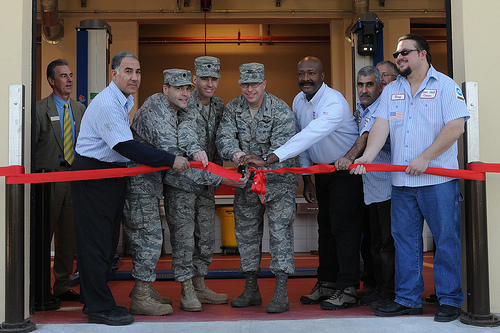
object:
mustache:
[299, 81, 315, 86]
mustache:
[360, 93, 371, 98]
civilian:
[70, 51, 190, 325]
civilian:
[30, 56, 86, 314]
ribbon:
[8, 160, 498, 194]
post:
[1, 166, 24, 330]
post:
[465, 160, 487, 322]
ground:
[199, 317, 463, 333]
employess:
[348, 34, 470, 322]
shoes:
[320, 285, 362, 310]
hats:
[162, 68, 195, 87]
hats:
[194, 55, 221, 78]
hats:
[238, 62, 265, 85]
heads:
[163, 69, 196, 110]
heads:
[192, 55, 221, 98]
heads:
[239, 62, 267, 103]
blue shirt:
[371, 65, 467, 186]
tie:
[61, 102, 77, 165]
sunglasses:
[393, 47, 426, 58]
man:
[283, 54, 355, 170]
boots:
[129, 280, 174, 316]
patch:
[455, 86, 465, 102]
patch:
[420, 89, 437, 99]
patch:
[391, 94, 404, 101]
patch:
[390, 111, 403, 120]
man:
[214, 62, 299, 312]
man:
[164, 55, 229, 310]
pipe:
[141, 35, 330, 44]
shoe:
[433, 303, 463, 323]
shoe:
[373, 304, 423, 317]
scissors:
[237, 165, 258, 180]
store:
[10, 0, 484, 323]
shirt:
[276, 82, 360, 165]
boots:
[265, 274, 289, 312]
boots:
[230, 271, 263, 307]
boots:
[192, 277, 228, 304]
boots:
[179, 280, 203, 312]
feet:
[265, 290, 288, 313]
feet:
[229, 290, 264, 307]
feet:
[196, 290, 232, 305]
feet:
[180, 293, 203, 311]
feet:
[127, 291, 173, 316]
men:
[122, 62, 223, 316]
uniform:
[214, 91, 297, 272]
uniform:
[163, 87, 224, 278]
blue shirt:
[75, 80, 136, 162]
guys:
[338, 62, 401, 314]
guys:
[376, 60, 399, 88]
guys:
[260, 55, 363, 309]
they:
[354, 31, 464, 321]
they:
[217, 54, 364, 312]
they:
[216, 36, 474, 317]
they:
[128, 53, 301, 314]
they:
[71, 44, 197, 324]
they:
[30, 51, 194, 320]